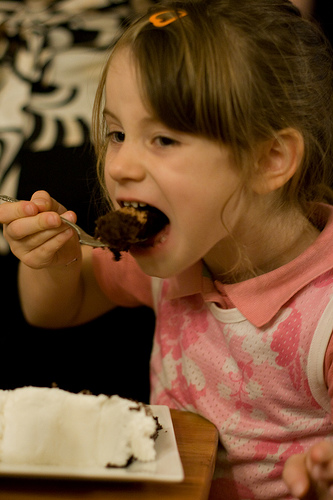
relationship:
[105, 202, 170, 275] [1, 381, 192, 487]
cake on plate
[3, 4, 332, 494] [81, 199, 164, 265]
girl eating cake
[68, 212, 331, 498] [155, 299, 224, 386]
shirt has print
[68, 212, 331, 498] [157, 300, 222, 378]
shirt has print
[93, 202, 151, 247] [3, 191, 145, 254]
cake on fork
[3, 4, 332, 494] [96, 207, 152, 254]
girl biting cake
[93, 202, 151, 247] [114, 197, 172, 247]
cake in mouth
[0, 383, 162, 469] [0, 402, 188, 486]
cake on plate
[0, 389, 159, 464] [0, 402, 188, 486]
frosting on plate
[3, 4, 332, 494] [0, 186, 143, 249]
girl holding fork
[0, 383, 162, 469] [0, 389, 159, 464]
cake with frosting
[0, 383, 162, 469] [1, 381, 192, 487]
cake on a plate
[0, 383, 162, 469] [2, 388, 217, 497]
cake on a table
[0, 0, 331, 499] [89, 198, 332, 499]
child wearing pink blouse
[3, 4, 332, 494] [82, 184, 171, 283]
girl eating cake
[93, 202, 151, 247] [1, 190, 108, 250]
cake on a spoon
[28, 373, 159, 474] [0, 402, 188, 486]
pastry on a plate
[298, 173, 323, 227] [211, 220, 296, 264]
hair hanging over neck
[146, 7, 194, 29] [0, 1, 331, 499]
barrette in hair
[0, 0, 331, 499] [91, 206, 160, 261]
child eating cake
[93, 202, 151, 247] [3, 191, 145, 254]
cake on a fork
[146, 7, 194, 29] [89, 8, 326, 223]
barrette in hair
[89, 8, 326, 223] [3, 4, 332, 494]
hair on girl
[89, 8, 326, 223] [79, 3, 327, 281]
hair on head